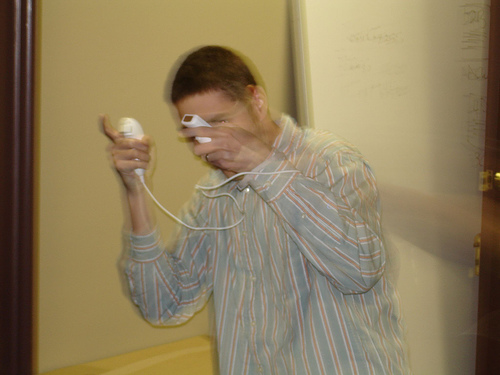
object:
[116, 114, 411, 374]
shirt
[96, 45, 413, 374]
man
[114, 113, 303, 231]
controllers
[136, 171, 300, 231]
cord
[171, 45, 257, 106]
hair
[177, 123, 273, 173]
hand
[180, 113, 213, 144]
wiimote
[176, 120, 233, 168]
fingers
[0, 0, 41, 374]
wood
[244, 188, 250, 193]
button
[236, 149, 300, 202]
cuff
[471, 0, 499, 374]
door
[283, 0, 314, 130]
shadow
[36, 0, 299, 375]
wall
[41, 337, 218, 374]
couch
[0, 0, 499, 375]
image